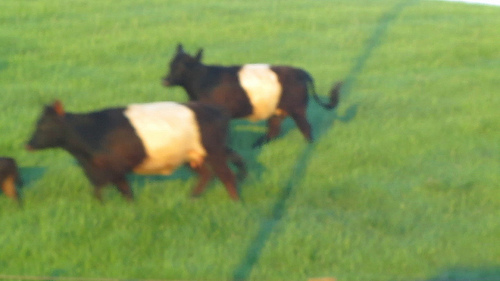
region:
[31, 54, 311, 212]
two cows on grass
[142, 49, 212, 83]
cow has black ears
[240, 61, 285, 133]
cow has white stomach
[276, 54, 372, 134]
cow has black tail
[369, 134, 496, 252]
grass is thick and green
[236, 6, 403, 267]
long shadow on grass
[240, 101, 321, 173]
cow has black legs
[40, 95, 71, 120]
cow has brown ear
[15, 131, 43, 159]
cow has black nose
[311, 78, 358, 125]
long tail is swishing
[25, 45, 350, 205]
Cows on the grass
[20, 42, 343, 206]
Cows are on the grass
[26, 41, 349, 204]
Black and white cows on the grass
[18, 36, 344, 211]
Black and white cows are on the grass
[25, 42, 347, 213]
Cows on the green grass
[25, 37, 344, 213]
Cows are on the green grass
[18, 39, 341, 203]
Black and white cows on the green grass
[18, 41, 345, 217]
Black and white cows are on the green grass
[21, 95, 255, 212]
Cow is on the grass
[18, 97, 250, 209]
Black and white cow is on the grass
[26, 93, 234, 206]
cow in the field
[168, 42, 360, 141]
cow in the field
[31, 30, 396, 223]
cows in the field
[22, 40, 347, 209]
two cows in a grassy field.